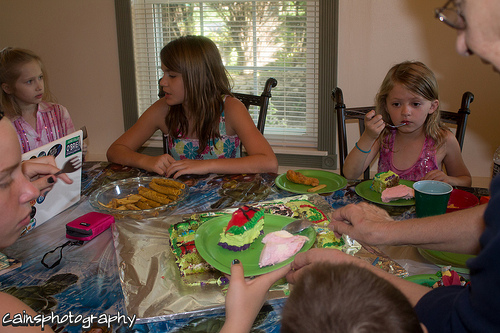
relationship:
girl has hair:
[99, 30, 279, 184] [154, 33, 232, 156]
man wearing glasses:
[286, 0, 500, 332] [428, 5, 475, 39]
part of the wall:
[370, 20, 425, 58] [12, 12, 484, 159]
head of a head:
[276, 258, 428, 332] [269, 256, 428, 323]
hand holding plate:
[223, 251, 295, 318] [186, 204, 319, 275]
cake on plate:
[216, 200, 265, 250] [190, 200, 318, 283]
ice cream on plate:
[255, 225, 302, 272] [190, 200, 318, 283]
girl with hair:
[99, 30, 279, 184] [158, 37, 237, 152]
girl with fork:
[337, 56, 476, 183] [365, 116, 410, 128]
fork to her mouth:
[365, 116, 410, 128] [396, 116, 416, 127]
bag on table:
[50, 201, 115, 247] [5, 157, 480, 323]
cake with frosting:
[216, 200, 266, 251] [222, 203, 260, 243]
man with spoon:
[323, 9, 484, 323] [283, 213, 336, 232]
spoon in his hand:
[283, 213, 336, 232] [325, 203, 393, 244]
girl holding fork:
[342, 60, 473, 187] [363, 97, 394, 120]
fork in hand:
[363, 97, 394, 120] [365, 111, 388, 141]